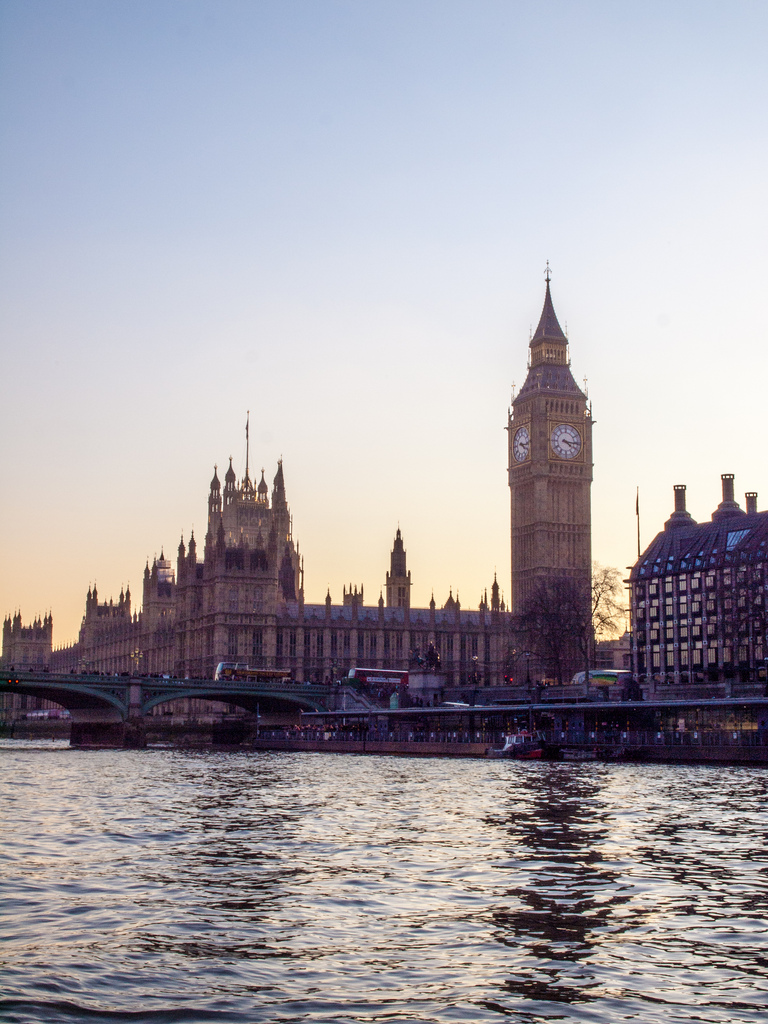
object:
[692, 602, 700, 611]
window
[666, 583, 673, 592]
window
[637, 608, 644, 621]
window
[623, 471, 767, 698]
building